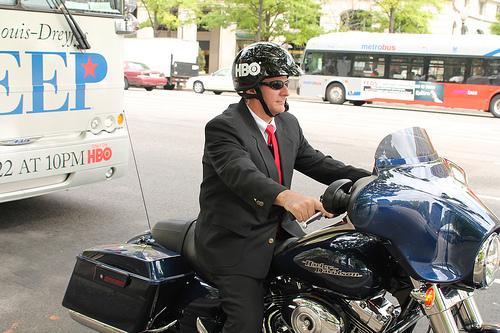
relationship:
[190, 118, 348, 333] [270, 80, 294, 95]
man wearing sunglasses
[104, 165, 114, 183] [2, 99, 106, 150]
light on front of bus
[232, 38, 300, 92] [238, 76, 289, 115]
helmet on head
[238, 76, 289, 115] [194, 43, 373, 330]
head on man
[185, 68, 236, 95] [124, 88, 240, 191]
white car on street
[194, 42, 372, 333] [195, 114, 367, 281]
man in a suit